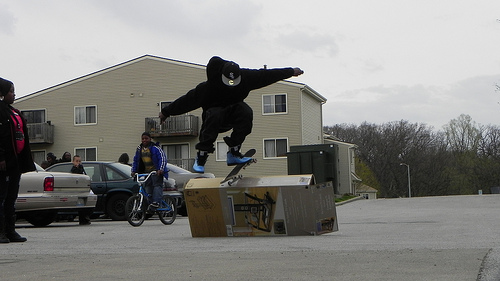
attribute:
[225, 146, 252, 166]
shoe — bright blue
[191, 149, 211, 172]
shoe — bright blue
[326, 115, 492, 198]
leafless trees — dense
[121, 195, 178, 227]
wheels — round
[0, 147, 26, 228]
pants — black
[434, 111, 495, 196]
trees — in background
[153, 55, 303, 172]
skateboarder — in the air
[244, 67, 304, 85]
arm — raised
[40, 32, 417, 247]
house — in the background